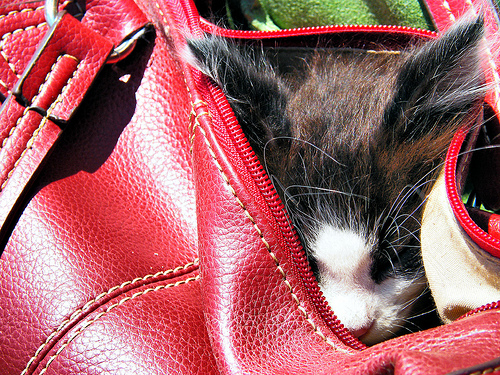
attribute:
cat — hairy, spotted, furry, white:
[171, 16, 464, 334]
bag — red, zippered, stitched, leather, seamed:
[0, 0, 500, 374]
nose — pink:
[331, 311, 390, 339]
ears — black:
[183, 11, 489, 114]